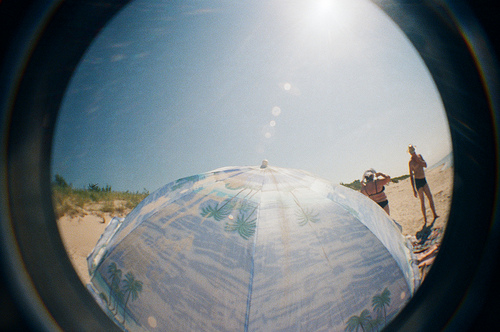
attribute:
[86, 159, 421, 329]
umbrella — blue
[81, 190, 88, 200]
grass — green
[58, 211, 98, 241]
sand — small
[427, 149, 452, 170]
water — in the background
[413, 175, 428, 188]
shorts — black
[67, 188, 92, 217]
grass — green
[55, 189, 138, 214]
grass — green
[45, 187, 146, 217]
patch — grassy